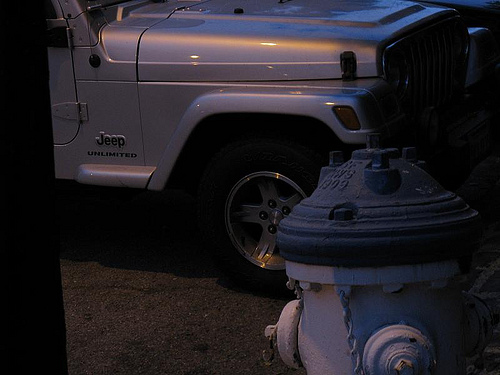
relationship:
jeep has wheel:
[2, 3, 495, 291] [185, 117, 367, 305]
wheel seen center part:
[185, 117, 367, 305] [226, 169, 292, 271]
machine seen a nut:
[2, 3, 495, 291] [255, 208, 270, 222]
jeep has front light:
[2, 3, 495, 291] [366, 25, 414, 95]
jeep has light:
[2, 3, 495, 291] [328, 97, 363, 136]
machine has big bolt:
[2, 3, 495, 291] [252, 205, 272, 221]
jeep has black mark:
[2, 3, 495, 291] [335, 49, 363, 83]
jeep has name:
[2, 3, 495, 291] [82, 129, 144, 164]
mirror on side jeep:
[32, 9, 74, 55] [2, 3, 495, 291]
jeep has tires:
[2, 3, 495, 291] [185, 117, 367, 305]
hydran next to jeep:
[248, 133, 480, 375] [2, 3, 495, 291]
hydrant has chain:
[248, 133, 480, 375] [331, 293, 369, 373]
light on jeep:
[77, 10, 403, 99] [2, 3, 495, 291]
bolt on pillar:
[259, 319, 281, 354] [248, 133, 480, 375]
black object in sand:
[184, 336, 215, 357] [65, 251, 271, 372]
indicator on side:
[328, 97, 363, 136] [2, 3, 495, 291]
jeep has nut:
[2, 3, 495, 291] [255, 208, 270, 222]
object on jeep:
[230, 4, 251, 19] [2, 3, 495, 291]